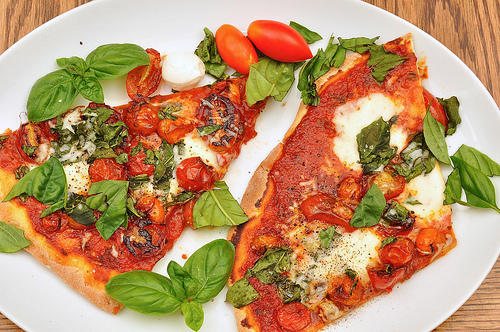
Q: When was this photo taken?
A: During the day.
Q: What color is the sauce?
A: Red.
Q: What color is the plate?
A: White.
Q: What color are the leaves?
A: Green.